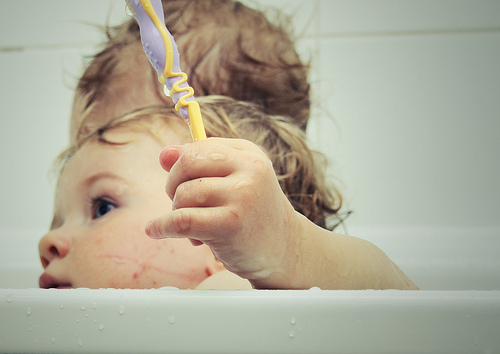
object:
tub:
[0, 286, 499, 354]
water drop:
[309, 285, 323, 293]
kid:
[37, 93, 416, 289]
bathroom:
[2, 0, 499, 353]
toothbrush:
[124, 0, 211, 145]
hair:
[46, 91, 356, 233]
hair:
[66, 0, 319, 140]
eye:
[89, 191, 125, 219]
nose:
[39, 225, 70, 268]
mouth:
[37, 272, 74, 289]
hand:
[144, 137, 294, 281]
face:
[31, 143, 218, 288]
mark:
[132, 272, 140, 278]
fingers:
[145, 205, 232, 240]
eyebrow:
[83, 170, 131, 186]